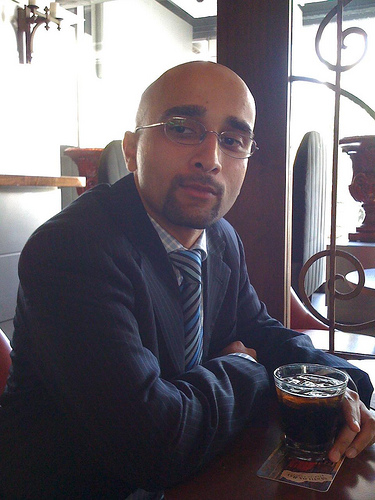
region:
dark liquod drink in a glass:
[270, 359, 347, 464]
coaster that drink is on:
[258, 444, 335, 492]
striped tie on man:
[159, 244, 213, 366]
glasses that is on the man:
[146, 117, 261, 157]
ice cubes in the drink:
[289, 368, 344, 392]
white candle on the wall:
[19, 4, 69, 65]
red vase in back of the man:
[63, 144, 98, 187]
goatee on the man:
[163, 171, 228, 223]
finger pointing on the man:
[339, 395, 366, 431]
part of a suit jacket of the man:
[32, 219, 189, 470]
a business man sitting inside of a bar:
[2, 60, 371, 498]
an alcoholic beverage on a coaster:
[274, 363, 349, 463]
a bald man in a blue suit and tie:
[2, 59, 374, 498]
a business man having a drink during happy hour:
[2, 58, 373, 498]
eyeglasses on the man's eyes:
[135, 114, 259, 160]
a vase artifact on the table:
[339, 135, 373, 242]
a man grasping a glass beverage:
[2, 60, 373, 464]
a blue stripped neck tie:
[170, 248, 204, 372]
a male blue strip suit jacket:
[6, 174, 374, 499]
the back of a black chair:
[291, 130, 325, 295]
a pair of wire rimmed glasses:
[132, 113, 265, 162]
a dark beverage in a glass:
[270, 360, 348, 465]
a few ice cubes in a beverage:
[279, 366, 345, 402]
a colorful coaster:
[255, 431, 352, 493]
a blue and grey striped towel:
[170, 257, 216, 371]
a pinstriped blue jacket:
[12, 169, 374, 496]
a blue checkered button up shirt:
[132, 216, 229, 376]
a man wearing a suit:
[16, 49, 373, 490]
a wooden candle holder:
[18, 0, 70, 65]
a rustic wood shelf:
[0, 166, 92, 194]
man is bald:
[114, 45, 253, 234]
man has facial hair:
[128, 60, 261, 241]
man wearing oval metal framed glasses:
[115, 43, 280, 262]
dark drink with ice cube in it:
[254, 320, 374, 491]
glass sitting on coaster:
[246, 354, 366, 495]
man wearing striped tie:
[28, 60, 266, 457]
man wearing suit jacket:
[15, 67, 351, 455]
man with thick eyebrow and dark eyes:
[108, 55, 267, 256]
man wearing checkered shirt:
[104, 57, 255, 282]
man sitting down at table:
[29, 53, 368, 483]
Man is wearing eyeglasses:
[131, 99, 267, 167]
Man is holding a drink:
[266, 349, 349, 465]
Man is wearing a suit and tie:
[0, 162, 369, 494]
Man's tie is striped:
[162, 241, 210, 380]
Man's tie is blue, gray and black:
[163, 240, 211, 377]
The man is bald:
[124, 46, 272, 118]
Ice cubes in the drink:
[271, 369, 346, 402]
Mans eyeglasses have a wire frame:
[133, 101, 262, 165]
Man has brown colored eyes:
[165, 121, 241, 151]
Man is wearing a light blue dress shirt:
[147, 212, 215, 292]